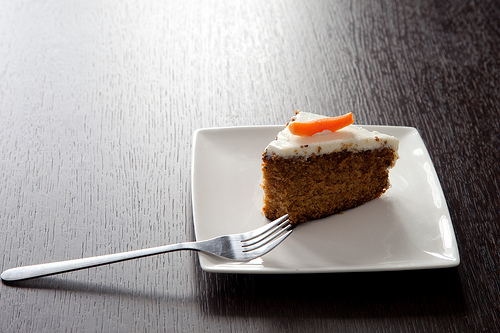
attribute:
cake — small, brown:
[264, 113, 395, 225]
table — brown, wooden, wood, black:
[2, 0, 499, 329]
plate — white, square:
[191, 123, 461, 268]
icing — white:
[266, 110, 400, 154]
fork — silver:
[2, 214, 292, 278]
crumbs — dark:
[294, 138, 389, 155]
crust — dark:
[270, 198, 368, 224]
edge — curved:
[0, 267, 15, 282]